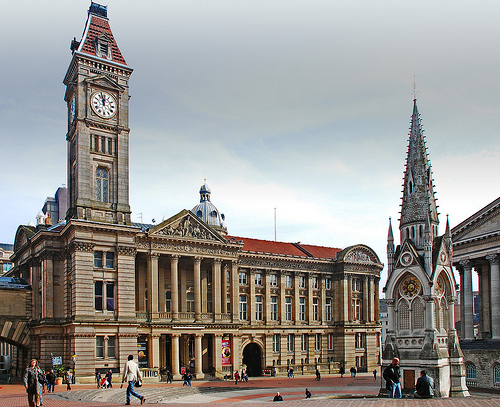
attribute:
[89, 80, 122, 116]
clock — white, large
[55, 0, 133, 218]
tower — long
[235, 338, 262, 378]
doorway — arched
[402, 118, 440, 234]
steeple — pointy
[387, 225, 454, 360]
building — top, tall, brown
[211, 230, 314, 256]
roof — shingled, dome, red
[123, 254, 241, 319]
pillars — 4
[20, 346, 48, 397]
woman — walking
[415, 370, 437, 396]
man — sitting, walking, standing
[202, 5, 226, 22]
sky — overcast, gray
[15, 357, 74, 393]
people — walking, standing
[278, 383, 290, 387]
sidewalk — red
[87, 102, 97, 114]
numerals — roman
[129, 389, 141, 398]
jeans — blue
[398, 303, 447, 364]
monument — tall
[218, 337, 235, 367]
banner — red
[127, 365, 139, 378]
top — white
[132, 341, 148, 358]
sign — white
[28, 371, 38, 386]
jacket — leather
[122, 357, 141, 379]
coat — gray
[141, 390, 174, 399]
street — brick